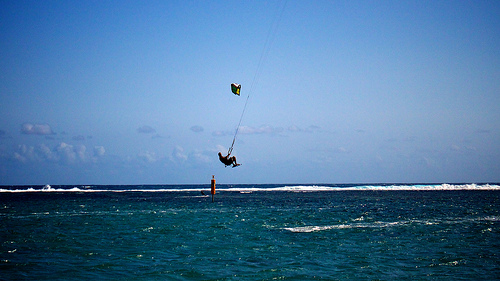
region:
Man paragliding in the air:
[209, 1, 300, 173]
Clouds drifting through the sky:
[5, 120, 498, 167]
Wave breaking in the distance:
[0, 178, 499, 195]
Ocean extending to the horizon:
[0, 171, 499, 278]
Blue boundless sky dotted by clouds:
[0, 0, 499, 188]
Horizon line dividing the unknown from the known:
[0, 179, 499, 189]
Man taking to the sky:
[215, 0, 290, 171]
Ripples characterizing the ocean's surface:
[222, 192, 496, 273]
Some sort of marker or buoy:
[204, 174, 219, 206]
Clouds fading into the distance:
[0, 126, 241, 171]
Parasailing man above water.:
[213, 78, 245, 166]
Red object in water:
[205, 170, 216, 195]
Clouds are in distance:
[5, 110, 210, 170]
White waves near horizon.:
[0, 182, 205, 192]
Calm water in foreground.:
[0, 202, 275, 272]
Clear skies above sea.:
[0, 5, 465, 70]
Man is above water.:
[212, 141, 237, 166]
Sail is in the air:
[225, 77, 245, 97]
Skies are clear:
[10, 0, 491, 62]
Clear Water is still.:
[35, 208, 265, 274]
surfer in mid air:
[209, 143, 243, 168]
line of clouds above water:
[9, 111, 336, 167]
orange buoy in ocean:
[204, 172, 217, 194]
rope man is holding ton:
[223, 26, 289, 147]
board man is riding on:
[227, 160, 244, 167]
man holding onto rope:
[216, 145, 241, 171]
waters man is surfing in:
[10, 175, 495, 275]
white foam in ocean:
[10, 180, 481, 235]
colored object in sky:
[228, 83, 242, 98]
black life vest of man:
[219, 158, 234, 163]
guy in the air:
[216, 149, 243, 169]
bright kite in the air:
[231, 80, 240, 98]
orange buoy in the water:
[210, 173, 217, 200]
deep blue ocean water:
[0, 182, 499, 279]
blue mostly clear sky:
[1, 0, 499, 184]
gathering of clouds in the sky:
[3, 120, 498, 178]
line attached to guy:
[226, 0, 291, 155]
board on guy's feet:
[230, 160, 243, 168]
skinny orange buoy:
[209, 175, 217, 204]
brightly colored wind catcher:
[228, 78, 240, 98]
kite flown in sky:
[215, 76, 255, 117]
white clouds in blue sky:
[5, 6, 51, 56]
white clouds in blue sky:
[20, 67, 70, 95]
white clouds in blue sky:
[14, 93, 64, 139]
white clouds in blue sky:
[74, 118, 161, 175]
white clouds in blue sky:
[92, 49, 167, 107]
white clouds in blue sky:
[127, 3, 217, 62]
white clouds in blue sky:
[261, 15, 311, 65]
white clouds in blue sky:
[283, 77, 328, 131]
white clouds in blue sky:
[314, 123, 362, 161]